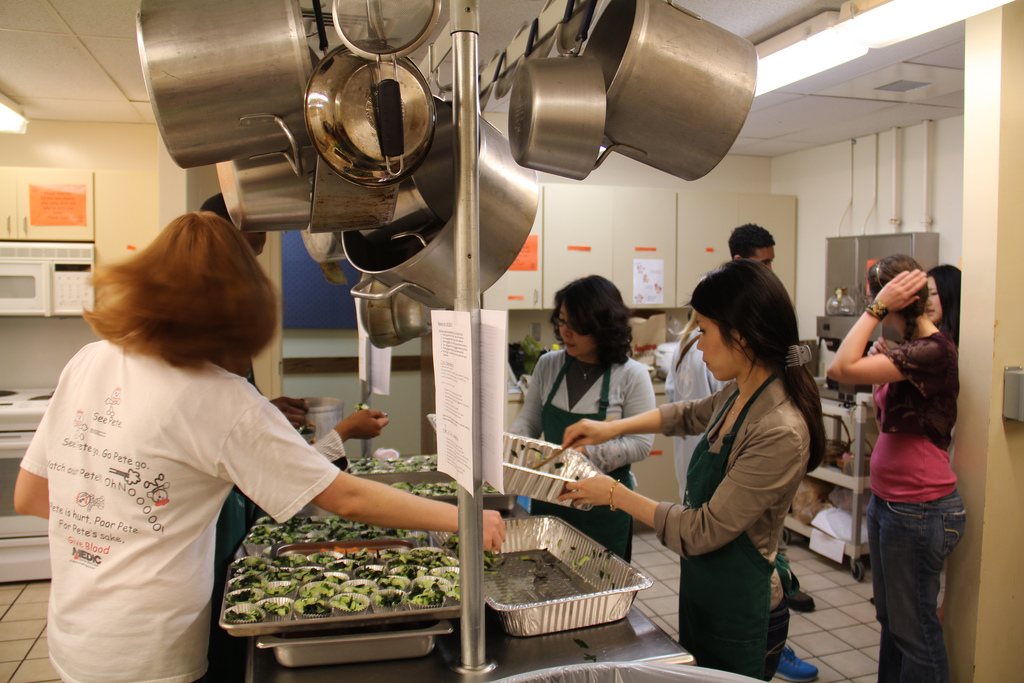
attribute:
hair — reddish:
[64, 202, 287, 388]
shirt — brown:
[643, 376, 804, 564]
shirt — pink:
[838, 336, 947, 535]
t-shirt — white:
[846, 331, 953, 507]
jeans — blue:
[853, 458, 957, 660]